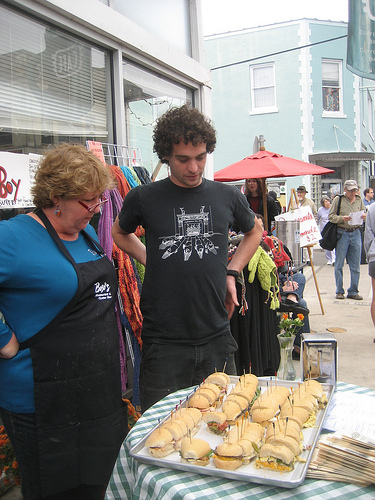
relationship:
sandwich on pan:
[245, 364, 345, 447] [130, 366, 335, 491]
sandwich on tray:
[251, 442, 301, 472] [235, 465, 308, 486]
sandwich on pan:
[250, 433, 295, 471] [130, 366, 335, 491]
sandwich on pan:
[143, 418, 174, 458] [130, 366, 335, 491]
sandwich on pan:
[176, 427, 210, 464] [130, 366, 335, 491]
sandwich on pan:
[181, 385, 212, 411] [130, 366, 335, 491]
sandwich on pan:
[301, 365, 328, 396] [130, 366, 335, 491]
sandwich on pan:
[147, 405, 201, 454] [130, 366, 335, 491]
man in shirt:
[326, 181, 366, 303] [326, 193, 364, 231]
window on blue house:
[321, 58, 342, 116] [186, 12, 372, 272]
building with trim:
[219, 38, 340, 134] [298, 28, 315, 153]